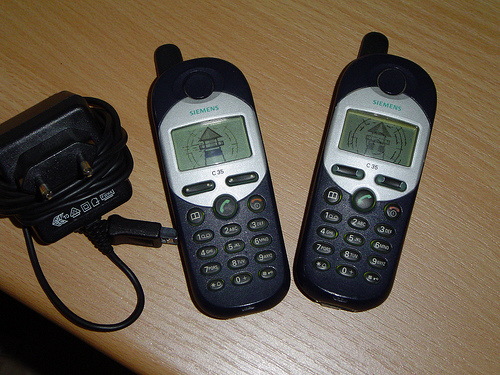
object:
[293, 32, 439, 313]
phone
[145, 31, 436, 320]
two phones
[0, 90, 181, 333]
charger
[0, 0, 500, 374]
table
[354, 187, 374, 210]
buttons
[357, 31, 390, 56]
antenna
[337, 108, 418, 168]
screen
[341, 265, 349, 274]
0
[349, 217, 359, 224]
2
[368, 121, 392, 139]
triangle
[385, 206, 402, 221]
button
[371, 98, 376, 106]
letters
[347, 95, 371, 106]
gray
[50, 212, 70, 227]
symbols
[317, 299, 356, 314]
port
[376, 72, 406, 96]
speaker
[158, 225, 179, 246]
usb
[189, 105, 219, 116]
siemens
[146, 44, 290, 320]
phone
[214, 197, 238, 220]
buttons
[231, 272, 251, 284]
0 button